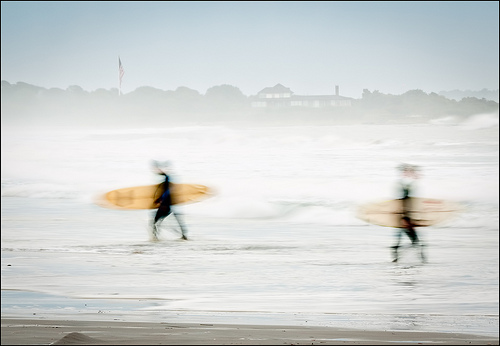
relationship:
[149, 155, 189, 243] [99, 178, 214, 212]
person has a surfboard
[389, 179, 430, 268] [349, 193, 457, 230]
person has a surfboard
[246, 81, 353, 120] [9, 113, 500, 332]
building near sea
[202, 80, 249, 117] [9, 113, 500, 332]
tree near sea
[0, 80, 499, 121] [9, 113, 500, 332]
tree near sea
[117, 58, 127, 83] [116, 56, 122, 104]
flag has a post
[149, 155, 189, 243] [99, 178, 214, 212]
person walking with a surfboard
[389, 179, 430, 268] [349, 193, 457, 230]
person walking with a surfboard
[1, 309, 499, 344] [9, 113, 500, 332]
sand near sea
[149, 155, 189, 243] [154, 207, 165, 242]
person has leg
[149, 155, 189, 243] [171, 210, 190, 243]
person has a leg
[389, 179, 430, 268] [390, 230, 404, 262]
person has a leg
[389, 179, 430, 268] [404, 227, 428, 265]
person has a leg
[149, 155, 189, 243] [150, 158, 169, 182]
person has a head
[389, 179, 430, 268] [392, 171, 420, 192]
person has a head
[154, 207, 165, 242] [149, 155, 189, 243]
leg of a person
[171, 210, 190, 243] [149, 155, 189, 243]
leg of a person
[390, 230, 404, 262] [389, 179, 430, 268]
leg of a person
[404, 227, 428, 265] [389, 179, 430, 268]
leg of a person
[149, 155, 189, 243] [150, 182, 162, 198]
person has an arm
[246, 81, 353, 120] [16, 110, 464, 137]
building on beach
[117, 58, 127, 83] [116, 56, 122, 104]
flag on post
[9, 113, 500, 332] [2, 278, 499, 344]
sea on shore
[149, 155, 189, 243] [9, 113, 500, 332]
person walking in sea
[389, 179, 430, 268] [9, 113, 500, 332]
person walking in sea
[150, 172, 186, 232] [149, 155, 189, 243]
wetsuit of a person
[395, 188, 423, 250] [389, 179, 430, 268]
wetsuit of a person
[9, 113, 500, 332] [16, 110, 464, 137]
sea on beach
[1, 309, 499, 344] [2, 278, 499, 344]
sand of shore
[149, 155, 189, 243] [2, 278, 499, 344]
person on shore